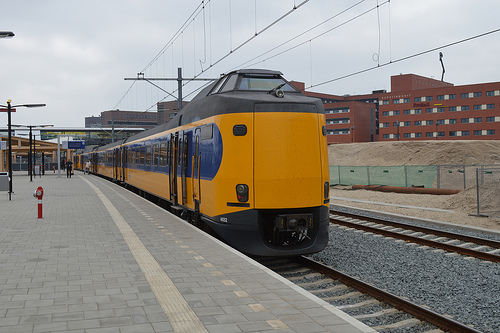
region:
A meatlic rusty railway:
[303, 254, 405, 331]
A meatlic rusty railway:
[339, 199, 400, 234]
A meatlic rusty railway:
[397, 214, 454, 261]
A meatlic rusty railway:
[461, 229, 497, 267]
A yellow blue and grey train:
[190, 74, 364, 270]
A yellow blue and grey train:
[122, 134, 187, 201]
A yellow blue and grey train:
[93, 141, 121, 178]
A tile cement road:
[52, 206, 124, 283]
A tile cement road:
[150, 233, 237, 325]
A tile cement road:
[46, 167, 114, 228]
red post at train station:
[36, 186, 44, 217]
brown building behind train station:
[322, 80, 497, 139]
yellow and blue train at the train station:
[67, 73, 329, 255]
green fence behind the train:
[332, 165, 440, 191]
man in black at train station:
[63, 157, 73, 177]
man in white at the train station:
[83, 158, 92, 173]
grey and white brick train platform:
[1, 169, 299, 330]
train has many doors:
[182, 132, 188, 207]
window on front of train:
[237, 74, 296, 91]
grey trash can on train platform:
[0, 171, 10, 191]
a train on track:
[66, 61, 333, 264]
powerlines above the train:
[77, 1, 499, 131]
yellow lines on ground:
[73, 166, 210, 327]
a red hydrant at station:
[28, 179, 45, 219]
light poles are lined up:
[0, 98, 65, 203]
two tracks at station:
[279, 206, 496, 332]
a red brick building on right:
[289, 69, 499, 139]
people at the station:
[47, 149, 93, 179]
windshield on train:
[223, 64, 294, 96]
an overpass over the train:
[35, 112, 148, 176]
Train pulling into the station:
[91, 97, 353, 248]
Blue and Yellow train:
[127, 110, 324, 217]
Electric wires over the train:
[130, 51, 265, 103]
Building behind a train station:
[364, 74, 494, 143]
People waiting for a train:
[65, 147, 105, 189]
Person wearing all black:
[61, 156, 85, 178]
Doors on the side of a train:
[161, 120, 207, 221]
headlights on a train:
[229, 167, 330, 213]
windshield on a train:
[263, 76, 295, 103]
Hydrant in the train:
[31, 174, 54, 222]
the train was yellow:
[52, 52, 375, 279]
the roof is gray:
[67, 62, 357, 269]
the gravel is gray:
[369, 237, 434, 287]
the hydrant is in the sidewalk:
[22, 174, 59, 236]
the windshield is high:
[225, 70, 300, 94]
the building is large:
[351, 77, 497, 140]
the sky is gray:
[36, 24, 107, 86]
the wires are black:
[165, 12, 340, 64]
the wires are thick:
[156, 0, 416, 68]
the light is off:
[17, 97, 49, 124]